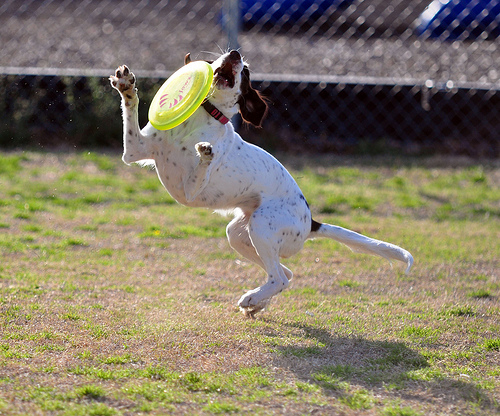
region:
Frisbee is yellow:
[138, 53, 220, 138]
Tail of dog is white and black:
[307, 211, 424, 274]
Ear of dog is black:
[235, 83, 272, 132]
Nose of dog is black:
[226, 44, 243, 63]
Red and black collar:
[198, 98, 235, 131]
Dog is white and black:
[99, 38, 422, 330]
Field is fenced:
[3, 1, 498, 56]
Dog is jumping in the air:
[93, 38, 429, 328]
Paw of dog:
[101, 61, 140, 99]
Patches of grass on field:
[0, 146, 499, 413]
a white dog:
[108, 31, 415, 322]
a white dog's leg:
[230, 205, 290, 312]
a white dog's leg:
[184, 127, 224, 198]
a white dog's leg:
[108, 65, 166, 172]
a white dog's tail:
[298, 215, 416, 280]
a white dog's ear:
[231, 78, 268, 130]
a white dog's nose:
[223, 44, 239, 64]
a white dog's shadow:
[267, 305, 476, 407]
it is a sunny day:
[3, 0, 496, 412]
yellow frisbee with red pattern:
[147, 59, 212, 127]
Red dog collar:
[190, 95, 237, 124]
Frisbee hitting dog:
[141, 45, 262, 130]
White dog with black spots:
[110, 45, 415, 315]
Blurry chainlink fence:
[0, 0, 496, 45]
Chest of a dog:
[126, 131, 263, 210]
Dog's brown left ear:
[236, 80, 266, 125]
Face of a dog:
[181, 47, 266, 124]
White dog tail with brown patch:
[310, 217, 411, 269]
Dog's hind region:
[226, 186, 311, 314]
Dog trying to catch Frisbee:
[105, 40, 416, 318]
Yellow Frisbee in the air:
[147, 58, 211, 128]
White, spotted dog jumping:
[110, 45, 410, 317]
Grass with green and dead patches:
[10, 233, 142, 375]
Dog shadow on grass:
[269, 313, 487, 414]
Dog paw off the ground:
[107, 62, 137, 95]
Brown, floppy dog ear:
[237, 82, 271, 128]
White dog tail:
[322, 220, 415, 272]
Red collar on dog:
[206, 102, 232, 127]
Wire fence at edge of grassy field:
[272, 0, 491, 159]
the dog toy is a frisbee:
[139, 55, 224, 135]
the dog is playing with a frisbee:
[85, 35, 443, 332]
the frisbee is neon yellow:
[140, 49, 216, 133]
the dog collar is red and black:
[207, 94, 236, 126]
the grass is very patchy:
[2, 302, 499, 412]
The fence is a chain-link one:
[283, 1, 498, 166]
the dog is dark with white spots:
[121, 142, 426, 326]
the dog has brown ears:
[240, 67, 276, 131]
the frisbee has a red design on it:
[154, 65, 196, 111]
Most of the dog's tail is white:
[324, 221, 417, 278]